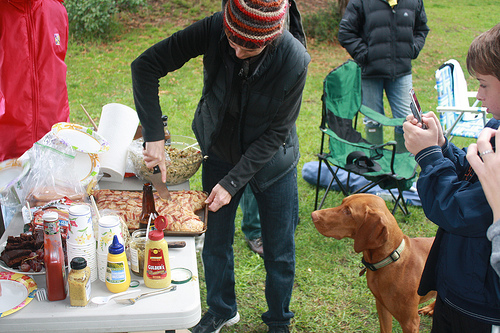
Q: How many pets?
A: One.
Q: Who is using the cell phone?
A: Boy.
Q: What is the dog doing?
A: Standing and staring.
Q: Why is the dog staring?
A: Food.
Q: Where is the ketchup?
A: On the table.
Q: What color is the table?
A: White.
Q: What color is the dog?
A: Brown.